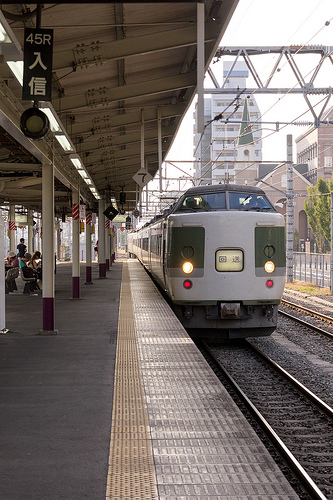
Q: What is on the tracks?
A: Train.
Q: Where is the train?
A: On tracks.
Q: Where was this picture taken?
A: Train Station.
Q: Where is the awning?
A: On the platform.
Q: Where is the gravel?
A: Between train tracks.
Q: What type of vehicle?
A: A train.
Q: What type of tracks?
A: Train tracks.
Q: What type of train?
A: A long train.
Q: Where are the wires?
A: Above the train.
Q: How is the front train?
A: Train has light on in front.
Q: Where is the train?
A: On tracks.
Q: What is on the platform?
A: Passengers.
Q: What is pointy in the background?
A: A church steeple.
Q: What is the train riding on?
A: Tracks.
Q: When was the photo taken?
A: Daytime.